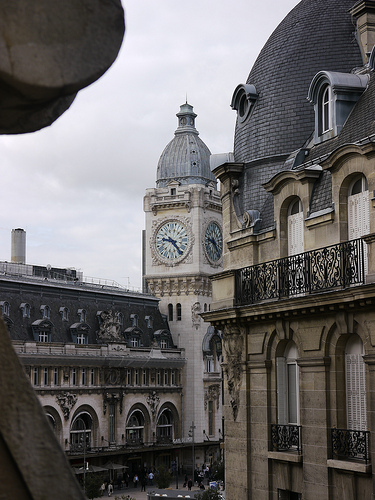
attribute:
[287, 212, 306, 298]
shutters — white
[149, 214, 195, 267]
clock — big 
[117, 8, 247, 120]
sky — cloudy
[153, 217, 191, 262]
clock — big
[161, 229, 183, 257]
hands — black